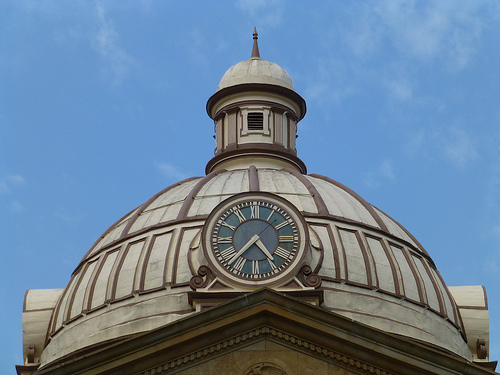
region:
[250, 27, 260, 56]
spire on top of building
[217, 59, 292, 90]
the shape is a dome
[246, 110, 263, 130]
vent on the side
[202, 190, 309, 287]
clock on the building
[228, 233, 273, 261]
clock hands are white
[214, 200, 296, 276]
the numbers are white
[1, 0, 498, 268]
sparse clouds in sky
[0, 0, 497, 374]
sky is nice and blue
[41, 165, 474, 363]
the roof is a dome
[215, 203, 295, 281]
clock face green and black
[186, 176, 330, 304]
A clock face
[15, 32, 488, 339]
The clock is on a building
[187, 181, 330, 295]
The time is 4:37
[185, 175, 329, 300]
The clock is circular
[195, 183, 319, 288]
The numbers are roman numerals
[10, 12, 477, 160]
The sky is behind the building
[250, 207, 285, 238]
The second hand on the clock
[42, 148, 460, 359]
This is a round dome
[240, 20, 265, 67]
Steeple at the top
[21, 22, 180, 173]
The sky is clear and blue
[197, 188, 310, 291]
The clock on top of the building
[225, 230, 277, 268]
The hands to the clock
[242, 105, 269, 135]
The vent on top of the building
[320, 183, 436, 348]
The building is the color brown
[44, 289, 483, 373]
The triangle part of the building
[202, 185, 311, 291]
The clock is round in shape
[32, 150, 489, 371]
The round shape on top of the building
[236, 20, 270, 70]
The very top of the building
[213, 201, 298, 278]
The numbers are roman numerals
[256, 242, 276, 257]
Silver hand on clock.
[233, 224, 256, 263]
Silver hand on clock.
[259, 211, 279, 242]
Black second hand on clock.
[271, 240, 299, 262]
Silver number on clock.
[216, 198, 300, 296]
Numbers are roman numeral on clock.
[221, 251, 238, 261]
Silver number on clock.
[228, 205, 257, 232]
Silver number on clock.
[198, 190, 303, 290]
Clock near top of building.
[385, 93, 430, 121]
Wispy white clouds in sky.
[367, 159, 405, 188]
Wispy white clouds in sky.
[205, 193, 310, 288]
clock is on dome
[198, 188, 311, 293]
clock reads 4:37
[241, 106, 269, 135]
window is on top of tower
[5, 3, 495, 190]
clouds float through the sky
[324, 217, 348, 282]
stripe is on side of dome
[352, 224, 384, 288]
stripe is on side of dome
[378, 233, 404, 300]
stripe is on side of dome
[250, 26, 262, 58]
point is on top of building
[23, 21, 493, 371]
dome is on top of building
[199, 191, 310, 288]
clock tells the time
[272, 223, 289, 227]
roman numeral on the clock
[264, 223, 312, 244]
roman numeral on the clock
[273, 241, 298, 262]
roman numeral on the clock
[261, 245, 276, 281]
roman numeral on the clock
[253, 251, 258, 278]
roman numeral on the clock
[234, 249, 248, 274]
roman numeral on the clock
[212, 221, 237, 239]
roman numeral on the clock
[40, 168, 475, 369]
a domed roof on a building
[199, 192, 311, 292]
a clock on a tower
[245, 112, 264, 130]
a vent on a tower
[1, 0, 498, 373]
a mostly clear blue sky